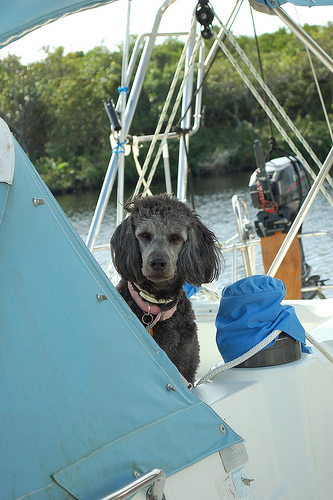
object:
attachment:
[33, 196, 45, 206]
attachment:
[97, 293, 108, 302]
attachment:
[166, 383, 176, 392]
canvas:
[0, 114, 247, 498]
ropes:
[233, 43, 308, 155]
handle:
[101, 468, 164, 499]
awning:
[0, 0, 120, 53]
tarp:
[214, 274, 313, 362]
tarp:
[0, 119, 244, 498]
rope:
[247, 0, 280, 143]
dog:
[110, 191, 222, 384]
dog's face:
[132, 211, 190, 281]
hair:
[132, 193, 182, 220]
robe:
[214, 275, 313, 370]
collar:
[131, 281, 174, 304]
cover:
[0, 1, 331, 498]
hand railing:
[96, 468, 162, 499]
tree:
[3, 43, 170, 195]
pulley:
[194, 0, 214, 40]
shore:
[54, 168, 332, 216]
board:
[260, 233, 300, 299]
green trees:
[229, 27, 331, 167]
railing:
[105, 468, 162, 500]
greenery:
[0, 64, 23, 117]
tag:
[148, 327, 154, 337]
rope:
[174, 34, 229, 136]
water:
[93, 189, 320, 277]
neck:
[126, 273, 186, 303]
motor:
[248, 154, 311, 238]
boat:
[2, 1, 327, 498]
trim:
[0, 3, 104, 45]